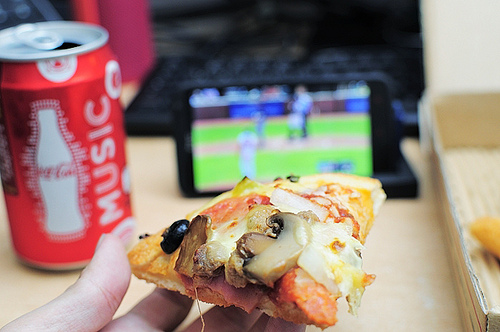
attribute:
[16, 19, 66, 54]
tab —  pop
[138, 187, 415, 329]
pizza — cooked, with mushroom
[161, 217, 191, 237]
olive — black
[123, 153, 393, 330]
pizza — cooked, a slice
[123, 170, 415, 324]
pizza — small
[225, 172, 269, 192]
pepper — yellow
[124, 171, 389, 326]
slice — triangular shaped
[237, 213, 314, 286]
mushroom — topping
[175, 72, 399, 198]
cell phone — black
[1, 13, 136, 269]
can —   aluminum, red, top opened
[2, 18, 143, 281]
can — topping, coca cola,  red ,   aluminum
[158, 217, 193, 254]
olive — black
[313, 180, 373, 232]
cheese — white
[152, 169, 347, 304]
pizza — supreme slice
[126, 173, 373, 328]
pizza — a slice, baked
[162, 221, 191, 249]
olive — black